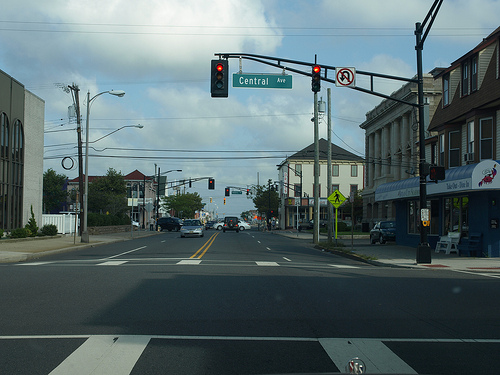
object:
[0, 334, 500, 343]
line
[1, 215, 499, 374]
road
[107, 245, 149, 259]
line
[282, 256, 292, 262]
line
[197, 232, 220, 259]
line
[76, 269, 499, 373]
shadow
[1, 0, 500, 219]
sky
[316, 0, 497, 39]
cloud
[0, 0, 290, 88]
cloud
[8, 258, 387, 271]
crosswalk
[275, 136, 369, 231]
house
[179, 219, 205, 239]
car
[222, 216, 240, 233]
jeep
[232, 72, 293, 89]
board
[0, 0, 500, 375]
town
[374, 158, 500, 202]
awning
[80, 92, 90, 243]
lamp post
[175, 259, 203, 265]
lines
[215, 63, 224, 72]
traffic light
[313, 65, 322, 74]
traffic light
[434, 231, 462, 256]
chair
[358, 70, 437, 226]
restaurant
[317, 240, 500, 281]
sidewalk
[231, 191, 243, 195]
sign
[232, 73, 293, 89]
street sign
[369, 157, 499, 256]
business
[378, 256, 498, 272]
corner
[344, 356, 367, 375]
logo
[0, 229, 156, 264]
sidewalk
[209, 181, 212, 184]
light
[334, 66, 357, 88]
sign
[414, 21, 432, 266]
post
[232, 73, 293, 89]
"central ave"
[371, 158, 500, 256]
store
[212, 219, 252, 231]
car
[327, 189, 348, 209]
sign